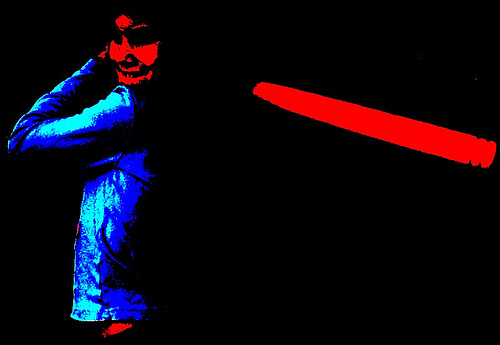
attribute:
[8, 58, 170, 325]
jacket — blue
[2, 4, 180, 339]
woman — thin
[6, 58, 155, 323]
jacket — blue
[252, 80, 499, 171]
sword — red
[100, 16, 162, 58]
eyes — dark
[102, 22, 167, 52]
eyes — black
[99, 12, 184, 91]
face — red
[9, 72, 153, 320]
shirt — blue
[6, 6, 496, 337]
area — black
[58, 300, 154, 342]
belt — red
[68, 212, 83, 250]
button — red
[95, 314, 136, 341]
part — red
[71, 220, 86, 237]
bit — red